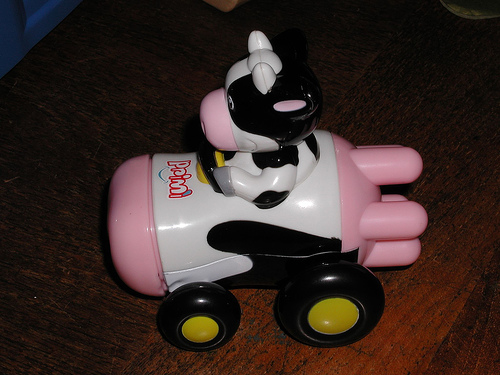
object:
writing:
[162, 154, 195, 204]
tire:
[153, 282, 244, 356]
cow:
[188, 25, 331, 210]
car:
[95, 23, 436, 355]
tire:
[271, 261, 388, 349]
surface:
[4, 0, 497, 371]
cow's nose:
[193, 89, 233, 154]